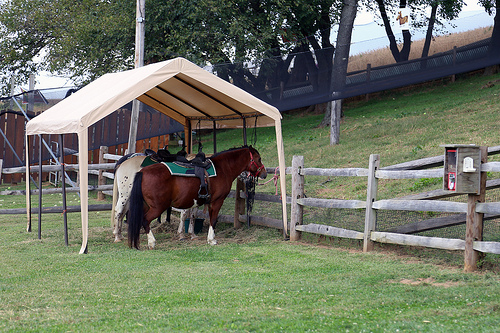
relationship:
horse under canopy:
[126, 144, 271, 252] [13, 46, 296, 246]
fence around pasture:
[0, 140, 500, 271] [1, 0, 498, 330]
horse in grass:
[126, 144, 271, 252] [123, 290, 371, 321]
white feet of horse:
[202, 225, 220, 248] [126, 144, 271, 252]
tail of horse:
[128, 171, 143, 250] [129, 152, 278, 250]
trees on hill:
[1, 0, 458, 100] [325, 6, 500, 187]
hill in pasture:
[325, 78, 461, 160] [50, 130, 439, 318]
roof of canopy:
[20, 46, 287, 128] [13, 46, 296, 246]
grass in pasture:
[157, 246, 276, 321] [1, 0, 498, 330]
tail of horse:
[128, 171, 143, 250] [126, 144, 271, 252]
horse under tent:
[126, 144, 271, 246] [13, 65, 298, 250]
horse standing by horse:
[126, 144, 271, 252] [112, 137, 150, 239]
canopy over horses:
[13, 46, 296, 246] [108, 144, 208, 237]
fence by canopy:
[0, 140, 500, 271] [13, 46, 296, 246]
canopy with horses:
[13, 46, 296, 246] [105, 141, 266, 246]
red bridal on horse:
[239, 146, 271, 185] [137, 131, 328, 253]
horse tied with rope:
[126, 144, 271, 252] [247, 166, 280, 195]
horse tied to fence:
[126, 144, 271, 252] [284, 147, 499, 274]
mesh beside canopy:
[1, 10, 498, 169] [13, 46, 296, 246]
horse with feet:
[126, 144, 271, 252] [139, 221, 226, 254]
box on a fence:
[430, 139, 487, 216] [341, 171, 487, 236]